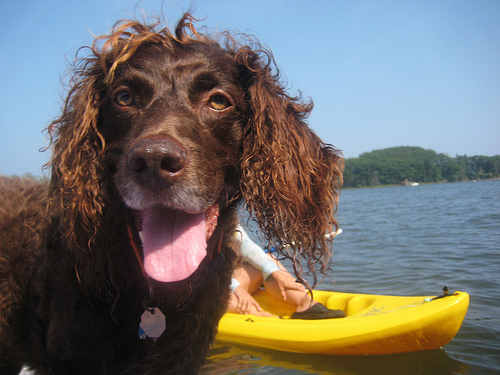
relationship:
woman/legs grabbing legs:
[224, 218, 312, 316] [231, 275, 313, 314]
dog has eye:
[0, 16, 351, 373] [203, 86, 236, 113]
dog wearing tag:
[32, 28, 409, 367] [130, 289, 205, 373]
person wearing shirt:
[225, 221, 344, 317] [226, 224, 283, 291]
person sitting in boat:
[225, 221, 332, 332] [231, 245, 476, 360]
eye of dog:
[200, 85, 230, 120] [0, 16, 351, 373]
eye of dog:
[110, 80, 142, 120] [0, 16, 351, 373]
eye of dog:
[200, 85, 230, 120] [10, 31, 364, 367]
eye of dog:
[110, 80, 142, 120] [10, 31, 364, 367]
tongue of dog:
[133, 206, 214, 285] [0, 16, 351, 373]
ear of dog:
[39, 50, 125, 317] [0, 16, 351, 373]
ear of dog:
[233, 35, 348, 298] [0, 16, 351, 373]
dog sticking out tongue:
[0, 16, 351, 373] [133, 206, 214, 285]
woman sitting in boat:
[228, 219, 313, 321] [213, 266, 470, 352]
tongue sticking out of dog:
[133, 206, 214, 285] [0, 16, 351, 373]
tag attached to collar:
[142, 301, 174, 346] [67, 221, 207, 356]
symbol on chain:
[134, 303, 170, 341] [102, 214, 182, 324]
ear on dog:
[233, 35, 348, 298] [0, 16, 351, 373]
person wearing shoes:
[225, 221, 344, 317] [288, 295, 343, 328]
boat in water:
[203, 266, 468, 352] [369, 199, 491, 267]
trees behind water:
[364, 144, 450, 190] [373, 190, 466, 280]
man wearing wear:
[206, 232, 322, 313] [288, 300, 348, 319]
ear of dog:
[39, 50, 149, 316] [0, 16, 351, 373]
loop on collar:
[140, 293, 160, 317] [120, 221, 231, 303]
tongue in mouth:
[133, 206, 214, 285] [123, 196, 222, 283]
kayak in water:
[216, 279, 468, 357] [201, 175, 496, 371]